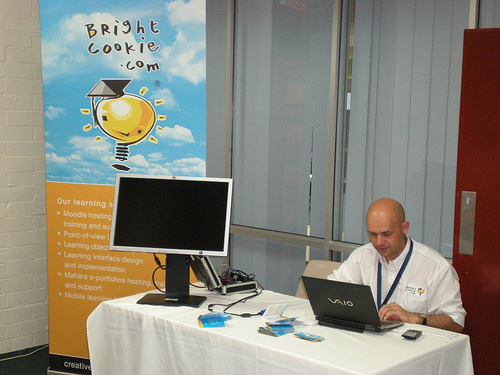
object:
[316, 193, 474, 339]
man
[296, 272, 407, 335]
laptop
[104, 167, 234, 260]
monitor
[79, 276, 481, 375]
table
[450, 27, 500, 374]
door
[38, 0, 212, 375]
bright cookie.com ad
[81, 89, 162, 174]
light bulb logo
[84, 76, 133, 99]
graduation cap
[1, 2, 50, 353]
wall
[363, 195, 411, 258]
head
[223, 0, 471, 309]
blinds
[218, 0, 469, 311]
window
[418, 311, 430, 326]
watch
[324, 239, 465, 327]
shirt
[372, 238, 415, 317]
ribbon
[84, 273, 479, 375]
table cloth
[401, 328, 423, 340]
cell phone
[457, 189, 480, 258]
handle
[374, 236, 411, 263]
neck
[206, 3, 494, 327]
wall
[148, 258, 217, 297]
cord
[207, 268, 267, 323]
cord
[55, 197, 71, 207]
words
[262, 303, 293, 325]
brochure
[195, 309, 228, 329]
brochure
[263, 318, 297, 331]
brochure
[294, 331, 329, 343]
brochure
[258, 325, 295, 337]
brochure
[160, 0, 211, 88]
cloud logo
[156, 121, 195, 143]
cloud logo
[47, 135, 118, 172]
cloud logo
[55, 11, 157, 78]
cloud logo